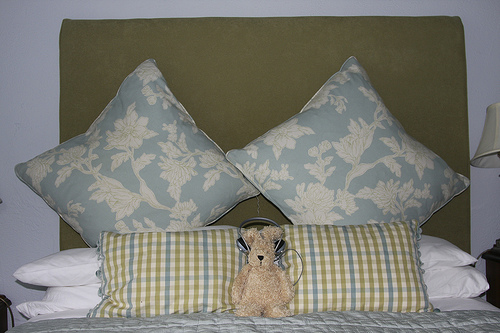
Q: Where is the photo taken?
A: Bedroom.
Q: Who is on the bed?
A: Stuffed animal.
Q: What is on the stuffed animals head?
A: Headphones.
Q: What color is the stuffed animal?
A: Brown.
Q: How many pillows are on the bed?
A: Eight.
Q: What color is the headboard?
A: Green.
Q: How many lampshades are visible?
A: One.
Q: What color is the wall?
A: White.